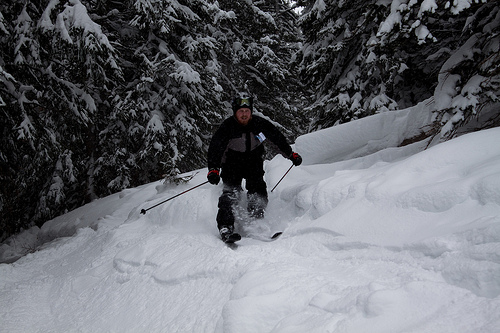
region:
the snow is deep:
[147, 164, 449, 320]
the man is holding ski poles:
[117, 140, 324, 227]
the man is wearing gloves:
[151, 144, 323, 184]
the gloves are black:
[160, 147, 318, 189]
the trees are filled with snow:
[248, 3, 479, 136]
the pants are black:
[202, 159, 284, 228]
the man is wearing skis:
[165, 79, 299, 264]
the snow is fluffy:
[298, 142, 480, 293]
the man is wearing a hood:
[215, 82, 259, 122]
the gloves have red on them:
[184, 147, 306, 185]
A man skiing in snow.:
[140, 95, 302, 244]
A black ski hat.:
[231, 93, 254, 118]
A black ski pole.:
[138, 174, 210, 216]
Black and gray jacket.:
[206, 114, 293, 171]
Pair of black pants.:
[214, 161, 269, 230]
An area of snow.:
[0, 95, 499, 330]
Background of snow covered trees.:
[0, 0, 499, 244]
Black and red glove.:
[206, 168, 221, 186]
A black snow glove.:
[290, 150, 303, 166]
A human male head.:
[231, 98, 255, 123]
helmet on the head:
[201, 85, 253, 107]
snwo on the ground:
[68, 278, 232, 330]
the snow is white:
[377, 268, 459, 313]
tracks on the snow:
[312, 278, 371, 310]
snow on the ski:
[272, 227, 293, 237]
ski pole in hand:
[140, 183, 235, 209]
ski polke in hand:
[242, 135, 317, 214]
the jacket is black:
[234, 147, 259, 174]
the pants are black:
[220, 203, 242, 225]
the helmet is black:
[237, 95, 257, 105]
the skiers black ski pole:
[138, 172, 220, 216]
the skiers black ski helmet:
[232, 91, 254, 111]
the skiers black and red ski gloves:
[207, 165, 222, 186]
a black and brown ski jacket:
[208, 114, 292, 166]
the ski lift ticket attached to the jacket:
[256, 130, 267, 144]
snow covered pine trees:
[253, 0, 497, 115]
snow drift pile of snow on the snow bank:
[305, 105, 495, 325]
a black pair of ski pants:
[215, 166, 267, 221]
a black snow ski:
[221, 227, 242, 245]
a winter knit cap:
[230, 94, 255, 110]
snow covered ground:
[0, 100, 497, 332]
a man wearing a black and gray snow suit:
[139, 91, 303, 244]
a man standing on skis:
[138, 90, 302, 241]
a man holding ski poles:
[138, 89, 303, 241]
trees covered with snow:
[0, 0, 499, 240]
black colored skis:
[220, 225, 282, 246]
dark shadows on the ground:
[224, 223, 344, 252]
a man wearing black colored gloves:
[206, 87, 304, 244]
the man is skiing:
[138, 90, 305, 247]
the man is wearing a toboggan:
[206, 91, 303, 238]